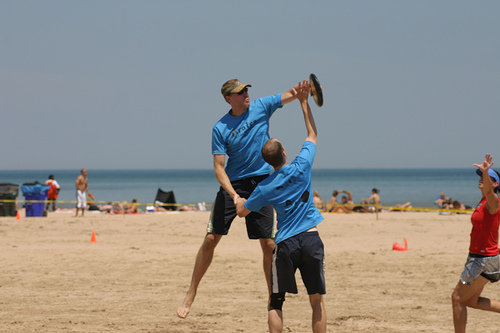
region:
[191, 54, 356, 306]
Two men fighting for a frisbee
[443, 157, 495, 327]
Woman in red shirt and shorts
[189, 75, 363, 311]
Two men in blue shirts and shorts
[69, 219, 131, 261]
Traffic cone in sand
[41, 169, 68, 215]
Man in red and white shirt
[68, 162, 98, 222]
Shirtless man in white pants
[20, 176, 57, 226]
Recycle bin in sand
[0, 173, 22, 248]
Black bin in sand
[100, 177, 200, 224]
Yellow crossing tape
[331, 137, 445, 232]
Beach shore with people sitting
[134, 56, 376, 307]
people playing with frisbee on beach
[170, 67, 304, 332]
guy jumping off sand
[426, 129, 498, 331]
lady reaching out with hand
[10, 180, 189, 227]
yellow tape barrier on beach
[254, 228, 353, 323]
black shorts with white stripe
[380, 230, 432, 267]
orange cone toppled on sand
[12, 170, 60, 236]
blue trash can with wheels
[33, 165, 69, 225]
person with orange and white shirt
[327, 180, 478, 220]
people laying on the beach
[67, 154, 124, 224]
guy wearing white shorts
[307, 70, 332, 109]
A black and gold frisbee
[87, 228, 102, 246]
An orange cone in the sand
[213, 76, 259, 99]
A cap on a man's head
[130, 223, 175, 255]
Sand on a beach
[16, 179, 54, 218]
A recycling trash can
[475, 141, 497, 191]
Hand reaching to catch frisbee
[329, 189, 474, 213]
People relaxing on the beach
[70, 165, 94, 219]
Man wearing white shorts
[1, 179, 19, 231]
A trash can on the beach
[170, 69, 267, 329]
A man jumping to catch a frisbee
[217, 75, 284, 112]
Person wearing gray visor.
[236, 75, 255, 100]
Sunglasses on man's head.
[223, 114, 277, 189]
Man wearing blue shirt.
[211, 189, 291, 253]
Man wearing dark shorts.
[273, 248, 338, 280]
Man wearing dark shorts.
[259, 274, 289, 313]
Black knee brace on man's knee.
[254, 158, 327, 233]
Man wearing blue shirt.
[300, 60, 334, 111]
Black frisbee near man's hands.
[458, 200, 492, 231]
Person wearing red shirt.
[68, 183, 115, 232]
Person wearing white shorts.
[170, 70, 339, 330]
two people reaching for a frisbee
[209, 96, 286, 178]
the man is wearing a blue shirt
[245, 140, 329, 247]
this man is wearing a blue shirt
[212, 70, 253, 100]
the man is wearing a baseball cap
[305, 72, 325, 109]
the frisbee is dark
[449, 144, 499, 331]
the woman is reaching up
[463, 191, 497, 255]
the man is wearing a red shirt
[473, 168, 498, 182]
the woman is wearing a blue hairband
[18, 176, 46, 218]
a blue trash can on the beach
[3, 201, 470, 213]
caution tape across the beach